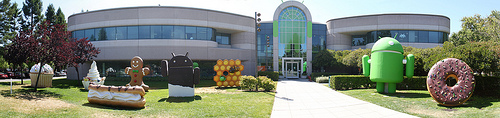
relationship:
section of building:
[284, 37, 312, 65] [247, 5, 352, 89]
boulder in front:
[307, 71, 339, 91] [272, 40, 332, 96]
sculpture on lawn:
[363, 22, 410, 94] [349, 96, 428, 114]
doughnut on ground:
[431, 52, 476, 89] [432, 103, 471, 116]